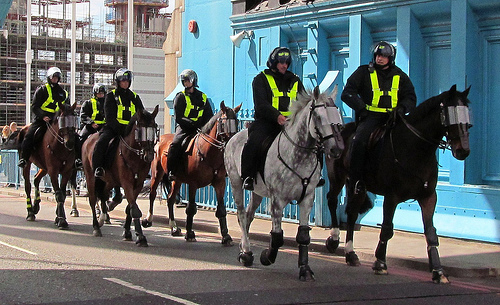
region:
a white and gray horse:
[227, 83, 342, 281]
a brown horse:
[149, 108, 234, 236]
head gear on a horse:
[310, 105, 343, 131]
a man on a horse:
[224, 46, 339, 284]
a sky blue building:
[189, 3, 426, 59]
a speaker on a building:
[224, 27, 256, 52]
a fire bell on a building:
[182, 22, 200, 35]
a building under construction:
[0, 4, 129, 59]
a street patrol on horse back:
[14, 36, 477, 285]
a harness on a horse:
[289, 96, 336, 204]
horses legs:
[252, 218, 325, 284]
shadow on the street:
[82, 263, 150, 299]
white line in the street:
[105, 263, 170, 303]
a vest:
[366, 73, 407, 108]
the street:
[32, 225, 106, 276]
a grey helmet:
[181, 68, 198, 80]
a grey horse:
[279, 150, 316, 193]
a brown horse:
[377, 142, 429, 189]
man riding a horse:
[169, 65, 217, 131]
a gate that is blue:
[2, 150, 27, 185]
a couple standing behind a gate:
[1, 121, 21, 190]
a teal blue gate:
[0, 105, 330, 226]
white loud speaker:
[231, 26, 256, 50]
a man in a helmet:
[340, 41, 417, 195]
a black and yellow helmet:
[265, 44, 292, 71]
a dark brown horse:
[321, 83, 473, 284]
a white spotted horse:
[222, 83, 344, 283]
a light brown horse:
[139, 100, 242, 247]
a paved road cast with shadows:
[0, 192, 499, 303]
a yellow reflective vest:
[263, 70, 300, 120]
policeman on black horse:
[323, 33, 476, 292]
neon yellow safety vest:
[363, 63, 404, 123]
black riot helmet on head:
[370, 39, 397, 71]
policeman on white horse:
[216, 46, 350, 283]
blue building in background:
[160, 1, 499, 251]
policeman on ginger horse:
[140, 67, 246, 250]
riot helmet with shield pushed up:
[110, 65, 136, 92]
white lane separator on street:
[2, 238, 207, 304]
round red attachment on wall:
[185, 17, 198, 36]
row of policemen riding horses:
[5, 34, 480, 291]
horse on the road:
[354, 96, 467, 283]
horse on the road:
[226, 99, 339, 247]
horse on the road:
[158, 108, 236, 254]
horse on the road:
[74, 118, 154, 254]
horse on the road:
[11, 119, 86, 228]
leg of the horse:
[367, 202, 409, 280]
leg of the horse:
[411, 201, 452, 291]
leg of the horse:
[294, 208, 321, 284]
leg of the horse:
[226, 198, 256, 260]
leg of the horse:
[184, 201, 200, 246]